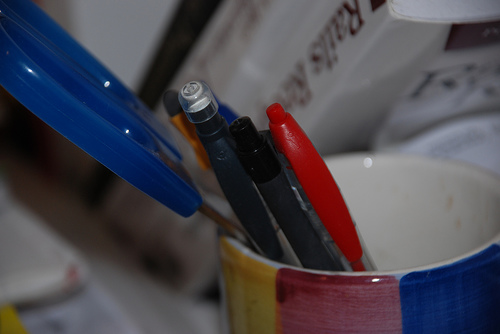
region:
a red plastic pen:
[256, 96, 378, 276]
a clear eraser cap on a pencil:
[171, 76, 222, 128]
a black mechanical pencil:
[171, 74, 289, 266]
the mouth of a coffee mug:
[214, 147, 498, 279]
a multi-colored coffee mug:
[202, 148, 498, 333]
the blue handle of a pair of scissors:
[0, 0, 207, 225]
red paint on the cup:
[273, 257, 408, 332]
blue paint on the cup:
[396, 240, 498, 332]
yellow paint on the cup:
[217, 227, 277, 332]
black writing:
[254, 0, 371, 130]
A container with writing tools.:
[160, 10, 494, 322]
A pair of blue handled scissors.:
[8, 4, 212, 241]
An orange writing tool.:
[275, 91, 370, 269]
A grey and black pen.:
[238, 105, 329, 275]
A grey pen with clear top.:
[173, 75, 269, 255]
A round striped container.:
[215, 142, 491, 332]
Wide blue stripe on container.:
[398, 262, 498, 329]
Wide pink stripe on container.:
[271, 258, 401, 332]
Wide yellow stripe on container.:
[213, 247, 278, 332]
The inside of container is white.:
[222, 157, 498, 293]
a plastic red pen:
[261, 93, 399, 280]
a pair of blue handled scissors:
[1, 15, 248, 268]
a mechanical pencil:
[153, 60, 284, 265]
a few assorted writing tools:
[167, 77, 409, 293]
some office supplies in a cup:
[21, 15, 493, 326]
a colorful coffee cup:
[180, 135, 499, 327]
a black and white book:
[218, 1, 489, 197]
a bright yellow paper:
[0, 301, 30, 332]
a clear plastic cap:
[176, 80, 226, 127]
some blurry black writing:
[277, 20, 371, 100]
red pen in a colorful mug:
[265, 91, 397, 268]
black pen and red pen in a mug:
[228, 101, 375, 272]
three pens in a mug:
[178, 78, 391, 273]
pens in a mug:
[165, 66, 498, 333]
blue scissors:
[0, 1, 257, 248]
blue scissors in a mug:
[2, 1, 258, 251]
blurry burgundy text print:
[300, 1, 381, 73]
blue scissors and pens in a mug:
[0, 1, 374, 332]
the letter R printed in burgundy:
[338, 1, 373, 37]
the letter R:
[340, 1, 365, 38]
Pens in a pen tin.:
[176, 72, 378, 271]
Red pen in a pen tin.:
[267, 100, 374, 275]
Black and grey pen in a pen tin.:
[229, 109, 319, 276]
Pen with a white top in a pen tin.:
[174, 80, 277, 262]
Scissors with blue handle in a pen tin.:
[4, 0, 259, 254]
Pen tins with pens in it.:
[184, 137, 499, 324]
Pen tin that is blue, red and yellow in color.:
[212, 230, 497, 322]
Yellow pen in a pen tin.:
[157, 85, 206, 172]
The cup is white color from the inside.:
[159, 77, 494, 296]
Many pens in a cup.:
[152, 68, 491, 316]